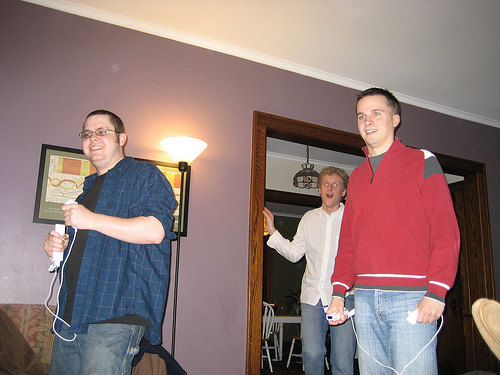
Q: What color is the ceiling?
A: White.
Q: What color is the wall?
A: Lavender.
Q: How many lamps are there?
A: One.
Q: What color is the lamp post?
A: Black.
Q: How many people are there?
A: Three.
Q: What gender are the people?
A: Male.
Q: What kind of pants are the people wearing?
A: Jeans.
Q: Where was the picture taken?
A: In a living room.